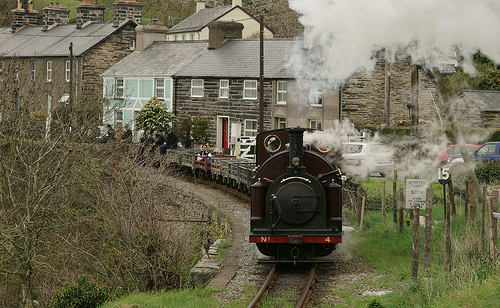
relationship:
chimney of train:
[285, 124, 312, 152] [164, 130, 345, 257]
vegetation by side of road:
[100, 285, 225, 306] [124, 128, 325, 305]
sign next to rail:
[399, 174, 430, 277] [246, 260, 318, 307]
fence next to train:
[346, 164, 498, 288] [126, 123, 351, 265]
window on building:
[191, 76, 207, 96] [175, 14, 453, 154]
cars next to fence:
[419, 153, 496, 182] [407, 161, 497, 260]